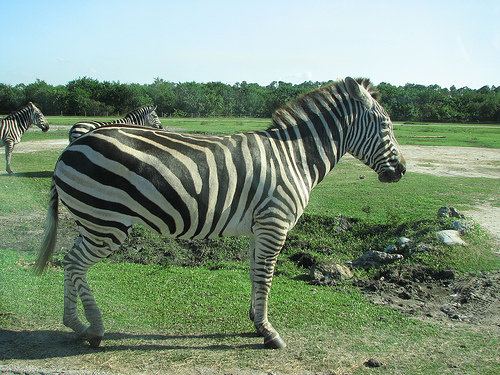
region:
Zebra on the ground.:
[28, 73, 413, 353]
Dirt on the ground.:
[369, 263, 499, 325]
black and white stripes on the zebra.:
[28, 78, 404, 351]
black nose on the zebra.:
[375, 152, 414, 188]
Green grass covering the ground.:
[2, 112, 498, 372]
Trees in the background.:
[0, 77, 498, 130]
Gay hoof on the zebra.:
[264, 333, 286, 353]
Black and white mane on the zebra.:
[265, 75, 377, 127]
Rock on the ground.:
[357, 246, 405, 267]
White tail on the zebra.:
[34, 186, 61, 282]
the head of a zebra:
[25, 99, 50, 136]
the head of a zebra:
[140, 99, 167, 132]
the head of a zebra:
[331, 69, 410, 191]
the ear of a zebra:
[340, 74, 375, 114]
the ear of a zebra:
[150, 101, 161, 113]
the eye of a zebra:
[377, 114, 392, 134]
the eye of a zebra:
[150, 111, 158, 121]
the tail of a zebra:
[21, 171, 60, 280]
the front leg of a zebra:
[240, 205, 287, 352]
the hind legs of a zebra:
[55, 207, 135, 347]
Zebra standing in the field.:
[23, 52, 402, 372]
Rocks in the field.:
[311, 228, 472, 323]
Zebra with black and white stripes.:
[21, 85, 476, 320]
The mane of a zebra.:
[251, 84, 370, 114]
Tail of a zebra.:
[32, 178, 59, 279]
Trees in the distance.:
[171, 79, 266, 126]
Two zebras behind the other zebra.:
[0, 95, 207, 165]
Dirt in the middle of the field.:
[404, 125, 496, 188]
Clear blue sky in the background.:
[88, 13, 413, 75]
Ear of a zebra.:
[346, 73, 365, 109]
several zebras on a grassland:
[1, 27, 451, 359]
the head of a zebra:
[325, 72, 418, 193]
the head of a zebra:
[130, 100, 168, 128]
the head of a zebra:
[24, 98, 50, 143]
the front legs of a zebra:
[246, 221, 291, 351]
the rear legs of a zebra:
[56, 235, 132, 352]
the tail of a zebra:
[25, 180, 60, 284]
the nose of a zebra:
[381, 140, 415, 191]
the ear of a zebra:
[341, 74, 370, 109]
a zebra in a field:
[32, 77, 405, 353]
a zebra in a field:
[60, 100, 167, 135]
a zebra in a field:
[0, 96, 45, 176]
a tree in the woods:
[462, 81, 495, 123]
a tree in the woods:
[410, 76, 446, 116]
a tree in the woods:
[178, 84, 222, 120]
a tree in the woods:
[150, 75, 173, 116]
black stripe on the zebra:
[53, 148, 180, 235]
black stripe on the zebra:
[50, 173, 165, 233]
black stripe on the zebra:
[57, 193, 127, 233]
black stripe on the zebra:
[68, 215, 120, 246]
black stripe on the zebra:
[91, 125, 196, 200]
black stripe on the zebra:
[235, 126, 261, 217]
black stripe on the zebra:
[277, 100, 327, 186]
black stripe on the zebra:
[295, 93, 331, 169]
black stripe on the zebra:
[310, 90, 342, 162]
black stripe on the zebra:
[317, 90, 349, 145]